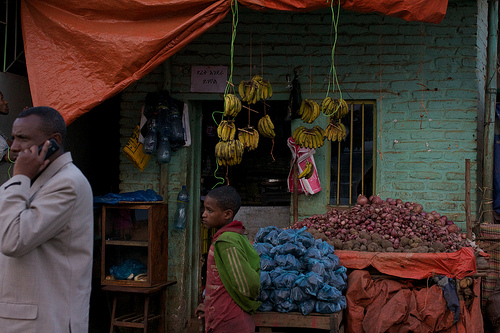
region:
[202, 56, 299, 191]
bananas hanging on a vine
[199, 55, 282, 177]
bananas are yellow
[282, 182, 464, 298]
fruit sitting in a stand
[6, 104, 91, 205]
man holding a phone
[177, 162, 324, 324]
little boy standing there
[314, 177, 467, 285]
the fruit is red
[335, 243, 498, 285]
tablecloth is red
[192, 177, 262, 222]
boy has black hair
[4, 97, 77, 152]
man has black hair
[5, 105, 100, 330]
person wearing tan jacket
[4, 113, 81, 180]
the man is talking on the phone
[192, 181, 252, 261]
the boy is standing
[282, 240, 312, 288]
the bag is blue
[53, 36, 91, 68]
the tarp is orange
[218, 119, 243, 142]
the banana's are yellow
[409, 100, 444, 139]
the building is green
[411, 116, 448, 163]
the building is made of bricks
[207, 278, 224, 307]
the shirt is red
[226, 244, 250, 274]
the jacket is gren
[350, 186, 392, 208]
the onions are red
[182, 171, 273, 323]
boy wearing a red and yellow t-shirt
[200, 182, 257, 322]
boy wearing a green and tan jacket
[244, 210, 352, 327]
pile of fruit in blue plastic bags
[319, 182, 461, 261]
pile of fruit at an open market stand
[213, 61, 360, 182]
bananas hanging at a fruit stand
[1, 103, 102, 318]
man wearing a tan suit jacket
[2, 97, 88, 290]
man holding a black cell phone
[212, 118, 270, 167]
bunches of yellow bananas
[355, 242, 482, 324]
red plastic under a fruit stand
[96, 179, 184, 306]
wooden crate with shelves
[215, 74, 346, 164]
bananas hanging in front of building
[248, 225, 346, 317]
a pile of blue tied bags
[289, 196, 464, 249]
a large pile of potatoes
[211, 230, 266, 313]
a green hoodie with stripes on arm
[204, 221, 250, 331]
a red shirt with yellow decal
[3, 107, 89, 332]
a man using his cellphone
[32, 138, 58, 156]
a black cellphone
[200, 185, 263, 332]
small boy standing in front of building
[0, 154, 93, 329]
a beige colored jacket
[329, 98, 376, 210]
bars over window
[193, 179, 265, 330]
a boy in a green jacket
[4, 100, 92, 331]
a man in a tan coat on a cellphone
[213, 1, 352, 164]
bunches of bananas hanging from green ropes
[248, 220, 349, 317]
blue bags on a wood table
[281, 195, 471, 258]
red vegetables on a wood table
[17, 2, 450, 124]
an orange tarp hanging down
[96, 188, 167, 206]
a blue tarp on top of a stand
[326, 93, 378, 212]
yellow bars on a window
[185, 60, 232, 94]
a white sign on the wall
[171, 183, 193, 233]
a blue bottle by the door jamb